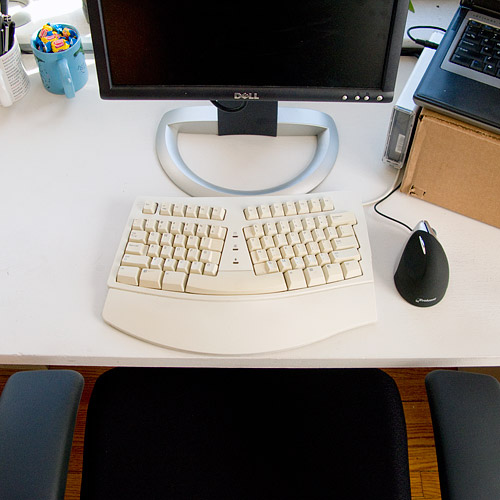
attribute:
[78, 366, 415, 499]
seat — black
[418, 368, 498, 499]
arm — blue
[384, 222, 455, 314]
mouse — black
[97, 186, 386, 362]
keyboard — white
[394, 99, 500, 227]
box — brown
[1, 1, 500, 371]
table — white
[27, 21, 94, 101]
cup — blue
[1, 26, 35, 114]
cup — white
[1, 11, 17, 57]
markers — black, white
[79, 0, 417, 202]
monitor — black, silver, dell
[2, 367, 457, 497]
floor — wood